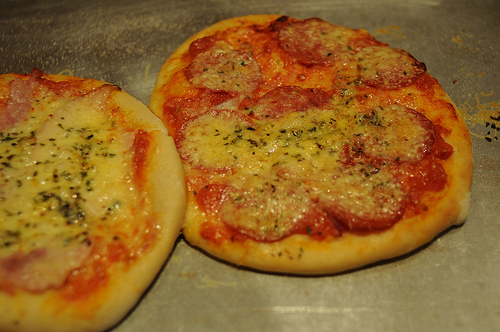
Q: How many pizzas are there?
A: Two.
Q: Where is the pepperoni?
A: On the pizza on the right.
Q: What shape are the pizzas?
A: Circle.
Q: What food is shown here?
A: Pizza.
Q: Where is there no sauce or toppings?
A: The crust.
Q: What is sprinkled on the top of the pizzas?
A: Herbs.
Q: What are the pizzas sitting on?
A: Metal surface.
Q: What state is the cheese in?
A: Melted.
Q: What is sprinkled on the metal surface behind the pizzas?
A: Flour.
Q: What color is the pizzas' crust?
A: Brown.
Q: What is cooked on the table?
A: The dough.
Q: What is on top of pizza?
A: Pepperoni.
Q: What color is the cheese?
A: Yellow.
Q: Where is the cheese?
A: On top of pepperoni.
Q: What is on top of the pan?
A: Pizza.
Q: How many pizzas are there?
A: Two.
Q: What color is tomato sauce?
A: Red.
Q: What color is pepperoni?
A: Red.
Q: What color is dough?
A: Beige.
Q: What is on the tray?
A: Pizzas.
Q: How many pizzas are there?
A: Two.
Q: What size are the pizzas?
A: Small.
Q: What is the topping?
A: Pepperoni.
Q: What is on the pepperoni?
A: Cheese.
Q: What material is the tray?
A: Metal.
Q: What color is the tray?
A: Gray.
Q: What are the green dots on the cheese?
A: Herbs.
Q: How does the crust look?
A: Crispy.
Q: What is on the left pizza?
A: Ham.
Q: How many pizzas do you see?
A: 2.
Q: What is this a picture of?
A: Pizzas.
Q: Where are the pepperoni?
A: On the pizza.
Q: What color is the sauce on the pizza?
A: Red.